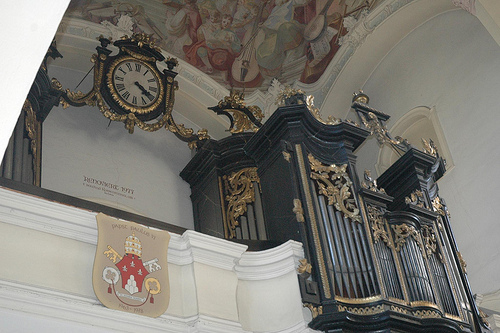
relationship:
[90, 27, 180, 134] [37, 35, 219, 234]
clock hanging on wall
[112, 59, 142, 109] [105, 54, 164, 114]
numerals on clock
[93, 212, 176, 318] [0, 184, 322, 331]
plaque hanging on wall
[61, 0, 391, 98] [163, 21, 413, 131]
design on ceiling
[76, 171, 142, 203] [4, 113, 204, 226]
writing on wall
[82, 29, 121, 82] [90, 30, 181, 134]
trim on clock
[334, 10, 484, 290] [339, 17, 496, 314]
paint on wall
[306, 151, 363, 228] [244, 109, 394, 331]
design on column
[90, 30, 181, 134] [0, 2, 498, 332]
clock inside of a building